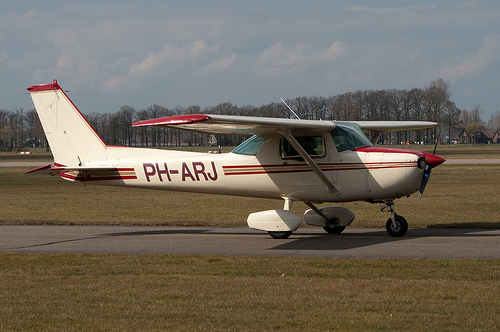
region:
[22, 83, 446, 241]
airplane is red and white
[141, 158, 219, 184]
plane has PH-ARJ on side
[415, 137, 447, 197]
red propeller on airplane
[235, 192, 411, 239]
landing gear on airplane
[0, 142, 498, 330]
grass is brownish green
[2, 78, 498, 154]
trees line background behind airplane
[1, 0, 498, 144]
sky is light blue and cloudy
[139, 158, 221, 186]
"PH-ARJ" written on side of plane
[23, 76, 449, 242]
A small white and red plane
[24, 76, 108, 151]
Tail of a small plane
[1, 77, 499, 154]
Many leaveless trees in the background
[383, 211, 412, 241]
A black round wheel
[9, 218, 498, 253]
Shadows on the ground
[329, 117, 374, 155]
Front window of a plane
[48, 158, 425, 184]
Red and yellow stripes on plane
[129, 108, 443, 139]
Wings of the plane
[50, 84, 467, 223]
the plane is white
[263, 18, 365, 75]
the cloud is white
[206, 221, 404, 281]
the road is gray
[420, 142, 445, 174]
the front is red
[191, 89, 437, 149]
the trees are tall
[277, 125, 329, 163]
side window on plane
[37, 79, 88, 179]
the tail of plane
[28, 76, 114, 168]
the tail is white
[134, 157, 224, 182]
the letters are red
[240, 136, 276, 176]
back window on plane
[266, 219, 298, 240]
wheel of plane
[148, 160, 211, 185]
letters on the side of the plane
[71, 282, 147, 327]
the brown grass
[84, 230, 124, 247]
the grey runway for the plane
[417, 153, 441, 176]
the tip of the plane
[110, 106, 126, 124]
the trees far away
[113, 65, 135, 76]
the clouds in the sky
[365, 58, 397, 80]
the blue sky in the distance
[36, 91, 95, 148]
the white tail of the plane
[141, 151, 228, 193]
the letters are red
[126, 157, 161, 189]
letter P on plane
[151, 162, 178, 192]
letter H on plane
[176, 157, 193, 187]
letter A on plane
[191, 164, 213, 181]
letter R on plane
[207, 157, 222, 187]
letter J on plane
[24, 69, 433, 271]
the plane is white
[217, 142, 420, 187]
red stripe on plane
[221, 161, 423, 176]
gold stripe on plane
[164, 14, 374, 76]
white clouds in sky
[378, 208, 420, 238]
front wheel of the plane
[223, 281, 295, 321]
the grass is brown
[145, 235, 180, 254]
the roadway